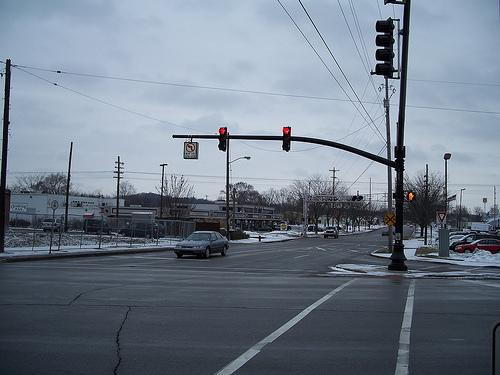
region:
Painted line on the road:
[243, 277, 373, 342]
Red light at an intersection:
[198, 122, 298, 154]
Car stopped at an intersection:
[168, 226, 240, 258]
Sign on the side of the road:
[377, 208, 398, 227]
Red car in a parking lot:
[455, 236, 499, 255]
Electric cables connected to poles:
[120, 73, 439, 155]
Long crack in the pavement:
[103, 298, 135, 373]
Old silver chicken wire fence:
[23, 213, 156, 260]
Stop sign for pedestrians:
[405, 188, 419, 203]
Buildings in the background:
[21, 188, 296, 234]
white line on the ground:
[228, 274, 357, 364]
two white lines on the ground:
[255, 280, 446, 355]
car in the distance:
[298, 215, 358, 259]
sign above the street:
[152, 133, 214, 188]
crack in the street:
[74, 293, 164, 358]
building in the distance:
[142, 173, 262, 250]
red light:
[205, 121, 226, 156]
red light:
[271, 112, 299, 180]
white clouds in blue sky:
[150, 42, 197, 89]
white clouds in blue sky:
[257, 32, 318, 82]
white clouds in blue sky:
[181, 42, 246, 102]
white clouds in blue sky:
[58, 21, 119, 58]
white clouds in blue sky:
[120, 31, 178, 72]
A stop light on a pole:
[280, 125, 291, 152]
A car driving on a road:
[175, 230, 230, 259]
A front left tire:
[202, 245, 212, 257]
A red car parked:
[455, 237, 498, 254]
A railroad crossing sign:
[384, 212, 396, 228]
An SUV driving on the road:
[322, 224, 339, 239]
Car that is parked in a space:
[40, 215, 65, 232]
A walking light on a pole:
[392, 190, 417, 202]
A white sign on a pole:
[183, 140, 200, 160]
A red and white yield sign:
[435, 210, 446, 223]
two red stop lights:
[192, 116, 313, 173]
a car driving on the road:
[137, 213, 258, 294]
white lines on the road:
[278, 256, 412, 373]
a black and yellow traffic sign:
[368, 210, 410, 235]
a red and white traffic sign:
[426, 198, 454, 238]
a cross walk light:
[378, 178, 427, 214]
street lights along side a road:
[206, 150, 262, 241]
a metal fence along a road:
[12, 197, 185, 257]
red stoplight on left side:
[219, 127, 227, 151]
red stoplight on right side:
[282, 126, 291, 151]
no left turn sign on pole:
[182, 141, 197, 158]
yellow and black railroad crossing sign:
[382, 211, 393, 224]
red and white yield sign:
[435, 211, 447, 222]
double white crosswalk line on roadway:
[211, 274, 418, 373]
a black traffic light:
[280, 126, 293, 152]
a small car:
[174, 228, 234, 257]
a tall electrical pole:
[111, 154, 131, 231]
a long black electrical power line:
[18, 63, 498, 117]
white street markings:
[218, 270, 426, 374]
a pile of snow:
[469, 242, 498, 261]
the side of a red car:
[455, 238, 497, 251]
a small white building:
[5, 188, 125, 220]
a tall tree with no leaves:
[220, 177, 267, 206]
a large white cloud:
[120, 0, 306, 91]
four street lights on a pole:
[375, 15, 394, 85]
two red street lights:
[216, 120, 290, 146]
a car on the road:
[180, 228, 226, 257]